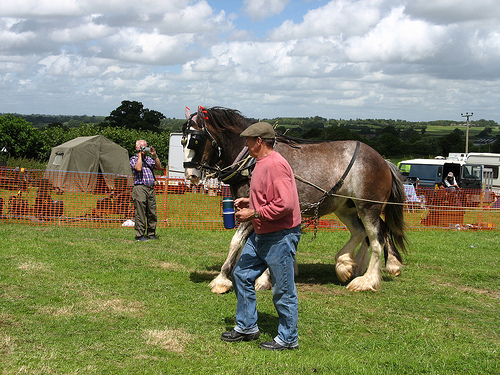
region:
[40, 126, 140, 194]
Tent with a window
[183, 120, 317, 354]
Man carrying a coffee mug in each hand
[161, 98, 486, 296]
Clydesdale horse in a field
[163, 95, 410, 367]
Clydesdale horse with red ribbons on its ears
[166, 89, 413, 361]
Man walking next to a Clydesdale horse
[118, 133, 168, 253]
Bald man using a gray video camera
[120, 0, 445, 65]
Cloudy sky with patch of blue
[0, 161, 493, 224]
Orange temporary fencing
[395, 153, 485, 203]
Person sitting in back of a blue van with white top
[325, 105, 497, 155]
A hill with a house green grass and trees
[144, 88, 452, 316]
a horse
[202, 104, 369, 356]
a horse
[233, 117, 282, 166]
the head of a man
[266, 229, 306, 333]
the leg of a man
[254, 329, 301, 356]
a black dress shoe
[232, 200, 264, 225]
the hand of a man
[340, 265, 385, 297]
the hoof of a horse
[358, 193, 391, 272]
the leg of a horse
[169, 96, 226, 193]
the head of a horse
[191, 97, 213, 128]
the ear of a horse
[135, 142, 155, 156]
a gray camera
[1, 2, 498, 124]
a cloudy blue sky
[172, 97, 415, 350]
Man walking with his big horse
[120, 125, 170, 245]
Man taking a picture of someone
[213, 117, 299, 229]
Man carrying his coffee cup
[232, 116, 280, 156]
Man wearing a stylish hat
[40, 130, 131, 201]
Tent set up in a field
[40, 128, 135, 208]
Tent with flap open in front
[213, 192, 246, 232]
Hands holding a coffee cup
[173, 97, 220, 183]
Head of a big horse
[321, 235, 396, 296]
Feet of a big horse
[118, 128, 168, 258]
Man using his new camera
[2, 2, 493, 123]
white clouds on a blue sky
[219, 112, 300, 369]
Older man in hat holding two blue cups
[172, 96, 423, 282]
brown and white horse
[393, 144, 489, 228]
blue van with white top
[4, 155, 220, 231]
orange checkered fence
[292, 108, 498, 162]
green trees and bushes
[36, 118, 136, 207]
green tent with open flap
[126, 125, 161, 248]
older man in blue checkered shirt recording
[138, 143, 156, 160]
video camera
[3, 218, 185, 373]
green grass with dried patches